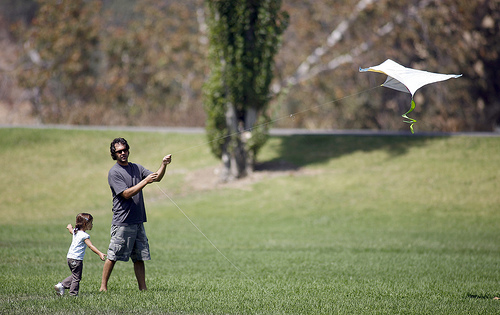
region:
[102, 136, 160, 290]
person in the grass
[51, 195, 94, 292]
person in the grass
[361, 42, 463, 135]
kite in the sky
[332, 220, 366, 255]
patch of green grass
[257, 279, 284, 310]
patch of green grass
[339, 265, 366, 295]
patch of green grass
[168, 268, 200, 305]
patch of green grass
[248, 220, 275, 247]
patch of green grass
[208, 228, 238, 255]
patch of green grass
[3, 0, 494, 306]
man and little girl flying a kite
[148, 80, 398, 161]
the kite string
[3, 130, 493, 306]
grass field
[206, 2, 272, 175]
tree in the grass field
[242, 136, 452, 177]
shadow of the tree in the grass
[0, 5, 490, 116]
shrubs with brown leaves on the opposite side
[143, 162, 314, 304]
kite string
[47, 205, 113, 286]
little girl playing next to man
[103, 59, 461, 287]
man is flying the kite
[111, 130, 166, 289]
person flying a kite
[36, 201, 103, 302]
little girl on the grass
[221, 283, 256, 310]
patch of green grass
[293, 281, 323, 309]
patch of green grass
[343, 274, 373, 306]
patch of green grass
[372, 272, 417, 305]
patch of green grass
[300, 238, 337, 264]
patch of green grass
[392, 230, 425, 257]
patch of green grass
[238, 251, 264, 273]
patch of green grass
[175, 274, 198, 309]
patch of green grass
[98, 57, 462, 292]
a man flying a kite in a park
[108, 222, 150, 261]
man wearing blue shorts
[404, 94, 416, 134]
a green ribbon on a white kite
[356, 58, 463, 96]
a white kite flying in the sky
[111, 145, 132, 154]
man wearing black sunglasses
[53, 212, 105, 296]
kid running in a field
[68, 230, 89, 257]
kid wearing a white shirt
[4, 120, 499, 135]
a road at the end of a park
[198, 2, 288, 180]
a green tree in a park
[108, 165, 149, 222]
man wearing a blue shirt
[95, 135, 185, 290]
man standing in the grass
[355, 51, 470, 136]
white kite flying in the air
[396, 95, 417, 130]
green ribbon hanging down from the kite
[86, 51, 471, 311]
man flying a kite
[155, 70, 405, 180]
thin white string hanging off the kite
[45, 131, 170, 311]
little girl standing by a man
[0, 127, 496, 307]
green grass on the ground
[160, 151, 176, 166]
fingers wrapped around the string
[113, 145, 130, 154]
sunglasses on the face